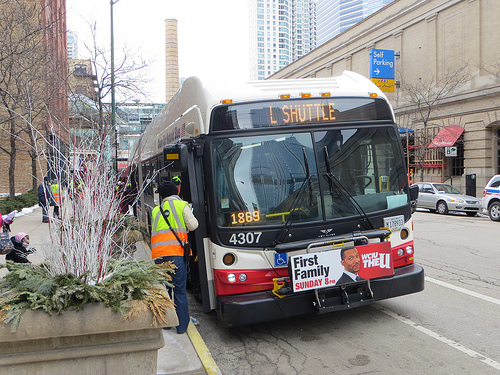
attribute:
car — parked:
[393, 167, 482, 226]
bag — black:
[158, 200, 195, 262]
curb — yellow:
[188, 316, 226, 373]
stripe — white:
[373, 302, 498, 369]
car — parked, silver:
[376, 167, 474, 229]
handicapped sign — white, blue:
[272, 250, 287, 269]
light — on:
[266, 104, 338, 123]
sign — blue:
[370, 42, 397, 84]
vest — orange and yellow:
[148, 175, 188, 270]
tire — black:
[425, 188, 452, 230]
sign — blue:
[370, 47, 396, 77]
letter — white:
[371, 49, 376, 56]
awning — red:
[425, 125, 467, 150]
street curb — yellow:
[164, 313, 220, 373]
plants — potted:
[9, 89, 183, 373]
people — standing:
[39, 153, 103, 229]